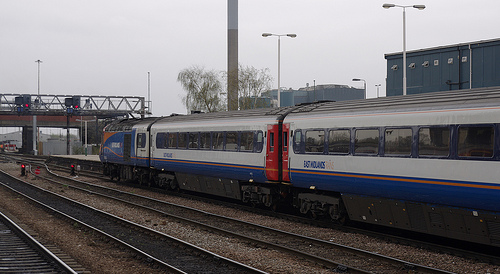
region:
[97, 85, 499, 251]
Blue and silver passenger train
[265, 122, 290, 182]
two red train doors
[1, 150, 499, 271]
Metal train tracks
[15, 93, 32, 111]
two train signal lights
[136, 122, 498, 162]
windows on a train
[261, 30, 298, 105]
Tall white lamp posts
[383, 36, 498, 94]
dark colored metal building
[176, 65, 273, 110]
trees growing next to train tracks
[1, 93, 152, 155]
overpass above train tracks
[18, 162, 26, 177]
light up train signal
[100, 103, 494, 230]
gray and blue train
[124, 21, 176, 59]
white clouds in blue sky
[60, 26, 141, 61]
white clouds in blue sky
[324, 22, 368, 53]
white clouds in blue sky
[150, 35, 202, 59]
white clouds in blue sky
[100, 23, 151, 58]
white clouds in blue sky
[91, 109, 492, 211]
white and blue train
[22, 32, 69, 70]
white clouds in blue sky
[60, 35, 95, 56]
white clouds in blue sky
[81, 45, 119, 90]
white clouds in blue sky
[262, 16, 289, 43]
white clouds in blue sky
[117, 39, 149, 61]
white clouds in blue sky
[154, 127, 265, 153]
windows on the train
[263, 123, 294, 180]
red doors on the train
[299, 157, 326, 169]
blue letters on the white train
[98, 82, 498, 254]
blue and white train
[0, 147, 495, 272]
black railroad tracks under the train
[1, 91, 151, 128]
bridge above the railroad tracks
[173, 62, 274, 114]
tree behind the train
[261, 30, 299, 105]
white street lights behind the train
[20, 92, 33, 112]
red train signal light on the bridge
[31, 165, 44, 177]
red and white circular sign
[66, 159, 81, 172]
Red light illuminated on post.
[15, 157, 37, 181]
Red light illuminated on post.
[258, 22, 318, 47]
Lights on top of pole.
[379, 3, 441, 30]
Lights on top of pole.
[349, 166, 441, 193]
Orange stripe on side of train car.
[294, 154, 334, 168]
Blue writing on side of train car.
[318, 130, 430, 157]
Windows a long side of train car.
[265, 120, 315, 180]
Red door on train car.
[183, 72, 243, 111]
Green leaves on tree in distance.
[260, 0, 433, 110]
two street lamp units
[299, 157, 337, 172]
company name on side of train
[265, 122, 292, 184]
two red doors for loading passengers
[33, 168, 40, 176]
red sign near red signals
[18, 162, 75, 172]
two red signals on ground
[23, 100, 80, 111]
two red lights mounted to bridge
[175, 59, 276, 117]
green trees on far side of train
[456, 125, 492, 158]
Window of a train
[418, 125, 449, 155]
Window of a train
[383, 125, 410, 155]
Window of a train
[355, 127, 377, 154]
Window of a train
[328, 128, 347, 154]
Window of a train